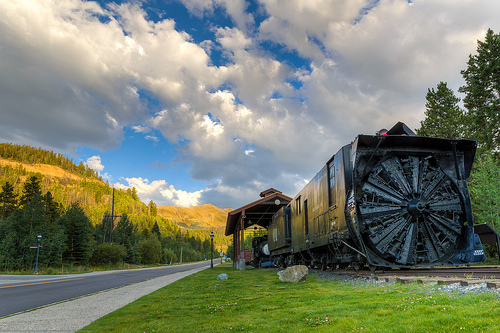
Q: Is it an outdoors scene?
A: Yes, it is outdoors.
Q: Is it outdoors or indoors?
A: It is outdoors.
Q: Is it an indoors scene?
A: No, it is outdoors.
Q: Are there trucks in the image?
A: No, there are no trucks.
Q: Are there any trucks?
A: No, there are no trucks.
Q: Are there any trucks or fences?
A: No, there are no trucks or fences.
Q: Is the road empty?
A: Yes, the road is empty.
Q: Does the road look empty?
A: Yes, the road is empty.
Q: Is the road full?
A: No, the road is empty.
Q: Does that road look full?
A: No, the road is empty.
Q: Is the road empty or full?
A: The road is empty.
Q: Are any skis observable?
A: No, there are no skis.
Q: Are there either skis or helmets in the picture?
A: No, there are no skis or helmets.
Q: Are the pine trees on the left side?
A: Yes, the pine trees are on the left of the image.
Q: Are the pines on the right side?
A: No, the pines are on the left of the image.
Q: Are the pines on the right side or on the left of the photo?
A: The pines are on the left of the image.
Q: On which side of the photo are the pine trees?
A: The pine trees are on the left of the image.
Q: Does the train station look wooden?
A: Yes, the train station is wooden.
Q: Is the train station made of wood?
A: Yes, the train station is made of wood.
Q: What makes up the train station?
A: The train station is made of wood.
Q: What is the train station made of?
A: The train station is made of wood.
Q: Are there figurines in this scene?
A: No, there are no figurines.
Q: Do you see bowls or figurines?
A: No, there are no figurines or bowls.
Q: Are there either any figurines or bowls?
A: No, there are no figurines or bowls.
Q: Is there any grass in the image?
A: Yes, there is grass.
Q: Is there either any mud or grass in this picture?
A: Yes, there is grass.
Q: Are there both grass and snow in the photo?
A: No, there is grass but no snow.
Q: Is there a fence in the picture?
A: No, there are no fences.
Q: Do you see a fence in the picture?
A: No, there are no fences.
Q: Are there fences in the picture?
A: No, there are no fences.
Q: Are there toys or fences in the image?
A: No, there are no fences or toys.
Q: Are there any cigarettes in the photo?
A: No, there are no cigarettes.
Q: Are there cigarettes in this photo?
A: No, there are no cigarettes.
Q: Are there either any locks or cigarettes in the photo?
A: No, there are no cigarettes or locks.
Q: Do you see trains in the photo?
A: Yes, there is a train.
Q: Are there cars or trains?
A: Yes, there is a train.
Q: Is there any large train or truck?
A: Yes, there is a large train.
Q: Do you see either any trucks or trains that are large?
A: Yes, the train is large.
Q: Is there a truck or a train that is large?
A: Yes, the train is large.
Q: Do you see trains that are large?
A: Yes, there is a large train.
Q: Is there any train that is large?
A: Yes, there is a train that is large.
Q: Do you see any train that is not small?
A: Yes, there is a large train.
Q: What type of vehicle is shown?
A: The vehicle is a train.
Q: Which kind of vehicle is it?
A: The vehicle is a train.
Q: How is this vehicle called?
A: This is a train.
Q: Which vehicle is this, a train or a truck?
A: This is a train.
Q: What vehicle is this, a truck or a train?
A: This is a train.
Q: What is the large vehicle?
A: The vehicle is a train.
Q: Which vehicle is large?
A: The vehicle is a train.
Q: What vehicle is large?
A: The vehicle is a train.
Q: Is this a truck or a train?
A: This is a train.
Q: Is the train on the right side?
A: Yes, the train is on the right of the image.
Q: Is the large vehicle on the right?
A: Yes, the train is on the right of the image.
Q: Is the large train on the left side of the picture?
A: No, the train is on the right of the image.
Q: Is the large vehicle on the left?
A: No, the train is on the right of the image.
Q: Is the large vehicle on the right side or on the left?
A: The train is on the right of the image.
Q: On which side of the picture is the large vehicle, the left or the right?
A: The train is on the right of the image.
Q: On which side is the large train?
A: The train is on the right of the image.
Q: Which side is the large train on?
A: The train is on the right of the image.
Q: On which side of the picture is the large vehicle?
A: The train is on the right of the image.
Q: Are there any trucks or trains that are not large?
A: No, there is a train but it is large.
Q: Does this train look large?
A: Yes, the train is large.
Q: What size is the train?
A: The train is large.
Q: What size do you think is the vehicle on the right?
A: The train is large.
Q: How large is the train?
A: The train is large.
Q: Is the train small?
A: No, the train is large.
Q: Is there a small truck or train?
A: No, there is a train but it is large.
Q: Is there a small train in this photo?
A: No, there is a train but it is large.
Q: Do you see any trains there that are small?
A: No, there is a train but it is large.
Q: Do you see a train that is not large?
A: No, there is a train but it is large.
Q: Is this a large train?
A: Yes, this is a large train.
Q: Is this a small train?
A: No, this is a large train.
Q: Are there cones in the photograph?
A: No, there are no cones.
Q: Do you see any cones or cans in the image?
A: No, there are no cones or cans.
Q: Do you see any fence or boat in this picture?
A: No, there are no fences or boats.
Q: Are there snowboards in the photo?
A: No, there are no snowboards.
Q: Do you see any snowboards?
A: No, there are no snowboards.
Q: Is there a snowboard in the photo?
A: No, there are no snowboards.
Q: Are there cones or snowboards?
A: No, there are no snowboards or cones.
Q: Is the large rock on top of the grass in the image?
A: Yes, the rock is on top of the grass.